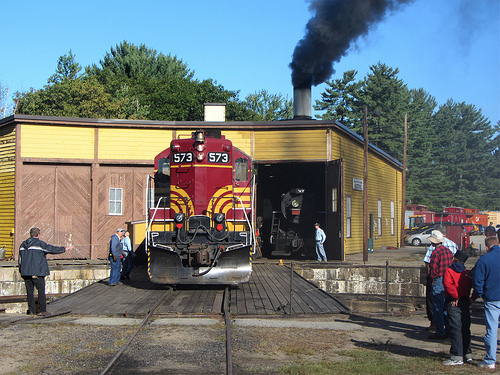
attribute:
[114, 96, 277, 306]
train — red, yellow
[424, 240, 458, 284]
shirt — red, plaid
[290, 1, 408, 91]
smoke — black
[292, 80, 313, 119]
smoke stack — silver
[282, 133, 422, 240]
siding — yellow, building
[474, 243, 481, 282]
shirt — blue